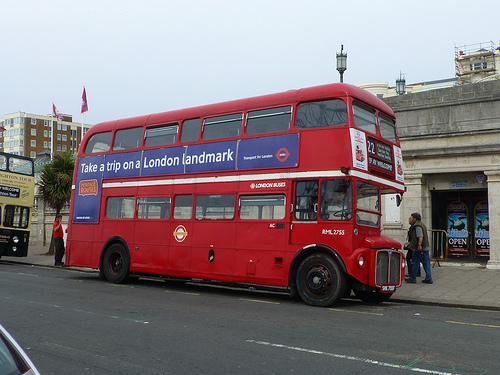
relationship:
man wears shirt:
[51, 213, 63, 266] [44, 197, 70, 249]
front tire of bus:
[352, 284, 392, 300] [65, 82, 407, 307]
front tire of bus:
[295, 252, 346, 307] [65, 82, 407, 307]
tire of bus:
[102, 235, 131, 279] [61, 82, 410, 309]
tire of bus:
[156, 276, 184, 288] [61, 82, 410, 309]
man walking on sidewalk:
[404, 212, 434, 284] [392, 261, 497, 299]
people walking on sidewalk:
[403, 212, 433, 285] [392, 261, 497, 299]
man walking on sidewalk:
[51, 213, 63, 266] [392, 261, 497, 299]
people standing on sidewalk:
[403, 212, 433, 285] [432, 260, 484, 301]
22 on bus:
[360, 133, 379, 154] [61, 82, 410, 309]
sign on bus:
[83, 145, 317, 185] [39, 62, 442, 338]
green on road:
[397, 347, 491, 374] [71, 322, 493, 372]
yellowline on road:
[433, 312, 498, 334] [23, 281, 381, 371]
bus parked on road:
[61, 82, 410, 309] [3, 261, 498, 372]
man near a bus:
[404, 212, 434, 284] [29, 61, 431, 323]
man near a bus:
[51, 213, 63, 266] [29, 61, 431, 323]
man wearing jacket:
[403, 211, 434, 284] [406, 220, 431, 249]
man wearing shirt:
[51, 213, 63, 266] [47, 81, 404, 304]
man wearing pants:
[47, 210, 70, 272] [47, 231, 68, 268]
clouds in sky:
[362, 7, 422, 63] [9, 11, 498, 147]